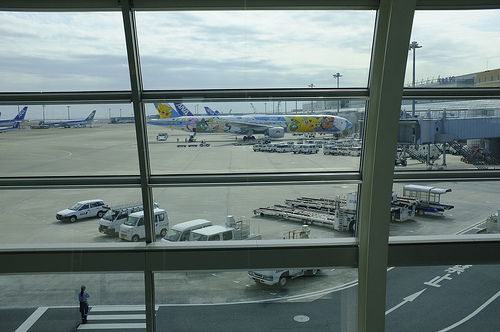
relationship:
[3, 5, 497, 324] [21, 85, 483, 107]
window has frames